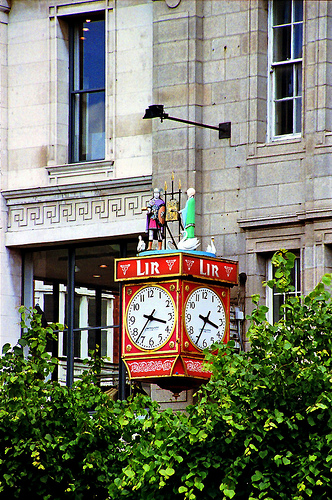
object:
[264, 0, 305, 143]
window frame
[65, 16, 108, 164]
window frame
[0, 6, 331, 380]
building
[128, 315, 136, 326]
number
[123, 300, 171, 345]
3:37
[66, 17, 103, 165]
window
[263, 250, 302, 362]
window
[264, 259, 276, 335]
white frame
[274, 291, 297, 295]
white frame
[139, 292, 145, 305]
black number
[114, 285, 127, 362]
edge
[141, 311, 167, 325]
hand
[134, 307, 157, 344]
hand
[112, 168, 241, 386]
gilded appointments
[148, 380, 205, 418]
metal pole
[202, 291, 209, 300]
number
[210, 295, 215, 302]
number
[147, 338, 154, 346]
number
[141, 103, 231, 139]
protruding light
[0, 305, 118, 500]
bush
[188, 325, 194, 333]
number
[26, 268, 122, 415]
fence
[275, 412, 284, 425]
foilage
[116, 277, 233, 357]
clock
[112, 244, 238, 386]
face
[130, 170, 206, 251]
interpretation sculpture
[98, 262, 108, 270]
lighting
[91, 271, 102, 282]
lighting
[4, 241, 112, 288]
ceiling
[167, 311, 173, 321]
black number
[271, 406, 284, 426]
leaf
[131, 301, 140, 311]
number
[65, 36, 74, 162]
edge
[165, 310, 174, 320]
number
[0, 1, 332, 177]
wall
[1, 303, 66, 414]
shrub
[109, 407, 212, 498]
shrub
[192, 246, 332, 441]
shrub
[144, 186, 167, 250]
figurine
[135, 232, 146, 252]
figurine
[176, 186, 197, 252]
figurine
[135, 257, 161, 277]
lir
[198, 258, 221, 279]
lir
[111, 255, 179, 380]
side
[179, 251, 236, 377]
side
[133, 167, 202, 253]
art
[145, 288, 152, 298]
number